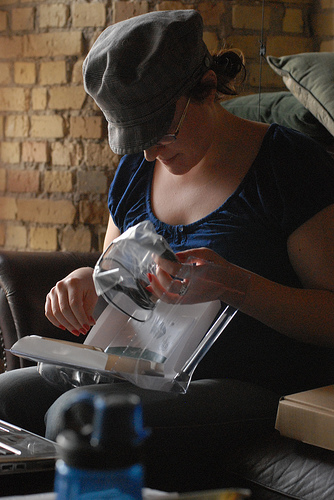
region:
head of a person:
[69, 2, 247, 183]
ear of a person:
[201, 69, 230, 114]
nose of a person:
[137, 138, 158, 168]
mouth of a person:
[153, 150, 188, 173]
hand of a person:
[129, 237, 229, 315]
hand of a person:
[36, 280, 105, 338]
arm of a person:
[219, 245, 332, 351]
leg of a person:
[32, 390, 293, 480]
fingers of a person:
[46, 306, 104, 338]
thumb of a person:
[165, 244, 210, 264]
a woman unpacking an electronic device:
[10, 7, 279, 396]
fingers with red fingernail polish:
[27, 264, 108, 340]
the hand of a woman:
[43, 265, 103, 337]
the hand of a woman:
[143, 242, 228, 306]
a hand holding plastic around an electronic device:
[97, 223, 243, 344]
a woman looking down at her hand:
[81, 17, 229, 291]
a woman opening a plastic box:
[46, 16, 226, 386]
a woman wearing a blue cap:
[67, 9, 237, 185]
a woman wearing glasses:
[78, 12, 242, 183]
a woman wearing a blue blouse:
[78, 12, 328, 369]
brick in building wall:
[53, 216, 96, 257]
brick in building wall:
[19, 217, 62, 253]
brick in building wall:
[2, 216, 32, 251]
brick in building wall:
[74, 196, 106, 223]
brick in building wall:
[15, 188, 77, 230]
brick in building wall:
[2, 194, 23, 221]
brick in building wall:
[71, 160, 116, 196]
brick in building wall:
[38, 163, 84, 199]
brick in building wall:
[3, 163, 48, 197]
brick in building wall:
[45, 128, 93, 171]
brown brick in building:
[85, 219, 111, 256]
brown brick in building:
[55, 218, 95, 254]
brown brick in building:
[23, 216, 59, 256]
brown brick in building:
[1, 218, 32, 253]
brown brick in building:
[71, 193, 113, 227]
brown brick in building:
[12, 191, 78, 230]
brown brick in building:
[1, 193, 27, 221]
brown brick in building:
[66, 160, 113, 201]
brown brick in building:
[33, 167, 78, 199]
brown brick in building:
[0, 162, 46, 197]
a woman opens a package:
[4, 13, 291, 408]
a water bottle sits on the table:
[41, 386, 155, 498]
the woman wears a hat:
[75, 1, 215, 155]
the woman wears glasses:
[130, 92, 203, 145]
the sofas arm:
[0, 245, 97, 370]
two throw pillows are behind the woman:
[231, 38, 333, 147]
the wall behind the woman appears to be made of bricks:
[4, 13, 333, 224]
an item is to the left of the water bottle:
[2, 417, 55, 497]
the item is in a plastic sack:
[91, 217, 172, 325]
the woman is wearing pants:
[1, 368, 282, 481]